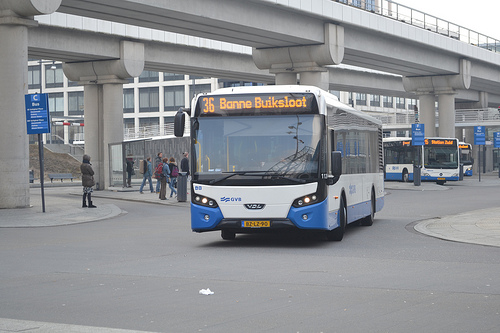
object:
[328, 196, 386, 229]
striped apron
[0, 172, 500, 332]
ground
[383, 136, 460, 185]
buses parked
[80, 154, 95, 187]
jacket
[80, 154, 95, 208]
woman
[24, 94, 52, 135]
sign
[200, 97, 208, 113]
number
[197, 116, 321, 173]
window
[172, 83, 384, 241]
bus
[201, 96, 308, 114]
print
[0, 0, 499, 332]
background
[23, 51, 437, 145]
white building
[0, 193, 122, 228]
sidewalk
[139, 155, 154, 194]
person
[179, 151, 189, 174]
person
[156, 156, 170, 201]
person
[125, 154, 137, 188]
person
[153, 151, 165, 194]
person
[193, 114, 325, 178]
windshield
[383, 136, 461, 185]
bus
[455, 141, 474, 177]
bus